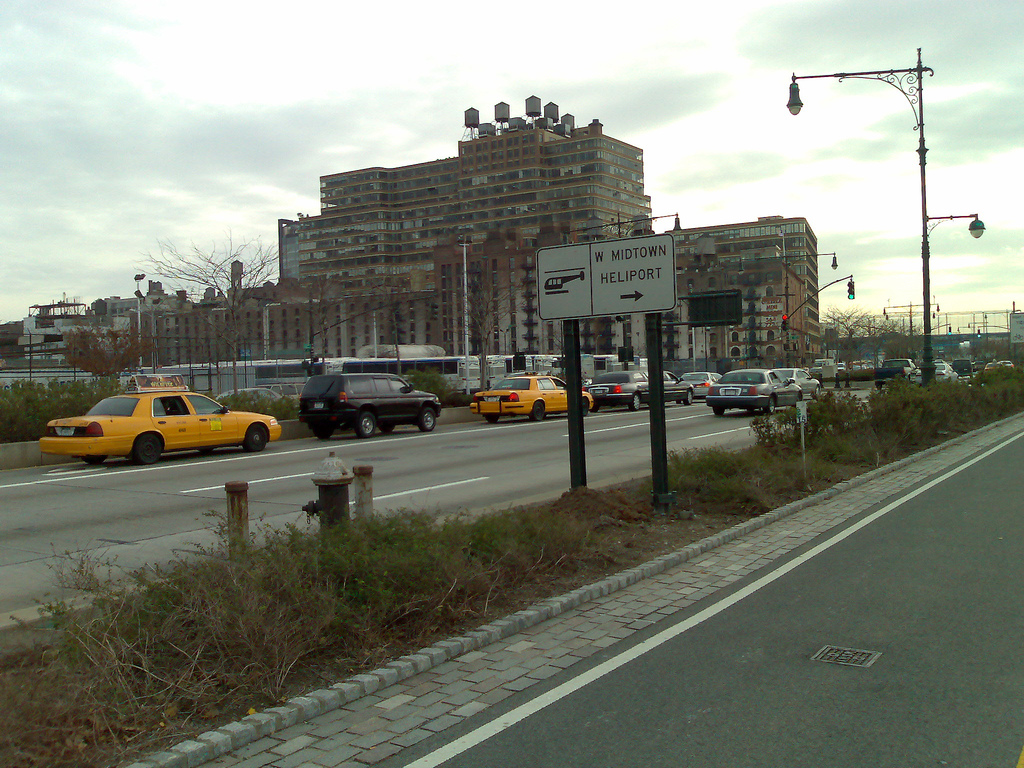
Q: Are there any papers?
A: No, there are no papers.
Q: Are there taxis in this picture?
A: Yes, there is a taxi.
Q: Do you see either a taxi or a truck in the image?
A: Yes, there is a taxi.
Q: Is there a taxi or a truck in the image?
A: Yes, there is a taxi.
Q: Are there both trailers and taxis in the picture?
A: No, there is a taxi but no trailers.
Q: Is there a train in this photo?
A: No, there are no trains.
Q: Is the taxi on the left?
A: Yes, the taxi is on the left of the image.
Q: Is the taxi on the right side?
A: No, the taxi is on the left of the image.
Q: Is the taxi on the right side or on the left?
A: The taxi is on the left of the image.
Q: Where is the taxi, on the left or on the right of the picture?
A: The taxi is on the left of the image.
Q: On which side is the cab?
A: The cab is on the left of the image.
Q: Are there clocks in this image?
A: No, there are no clocks.